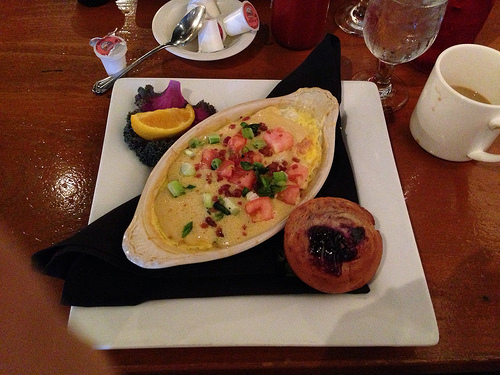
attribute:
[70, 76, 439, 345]
plate — white, square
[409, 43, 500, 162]
coffee cup — white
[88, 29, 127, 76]
packet of creamer — white, empty, opened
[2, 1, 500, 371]
table — wooden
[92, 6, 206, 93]
spoon — silver, stainless steel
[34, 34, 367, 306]
napkin — black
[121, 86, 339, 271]
dish — white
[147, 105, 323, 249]
food — colorful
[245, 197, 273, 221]
tomato — chopped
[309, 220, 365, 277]
jam — purple